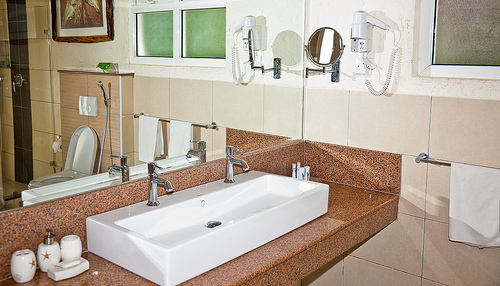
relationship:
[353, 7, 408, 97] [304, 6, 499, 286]
hair dryer on wall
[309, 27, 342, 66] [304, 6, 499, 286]
mirror on wall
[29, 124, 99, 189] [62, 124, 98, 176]
toilet has a lid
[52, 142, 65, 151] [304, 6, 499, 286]
toilet paper on wall